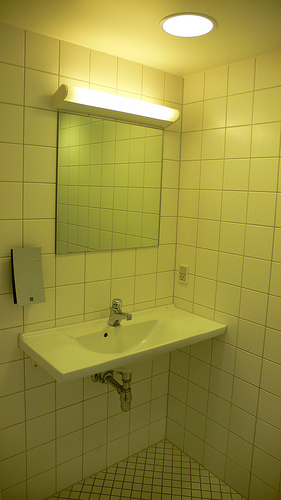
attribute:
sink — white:
[18, 303, 227, 385]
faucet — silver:
[107, 299, 132, 327]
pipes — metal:
[91, 366, 134, 412]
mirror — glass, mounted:
[55, 112, 164, 255]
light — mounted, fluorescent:
[53, 83, 180, 131]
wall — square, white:
[1, 23, 185, 499]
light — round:
[161, 13, 216, 38]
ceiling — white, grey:
[0, 0, 280, 78]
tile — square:
[163, 458, 173, 467]